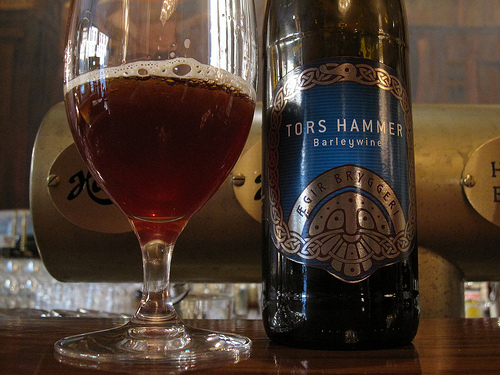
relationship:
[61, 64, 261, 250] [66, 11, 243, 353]
wine in glass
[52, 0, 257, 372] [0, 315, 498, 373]
glass on wood counter